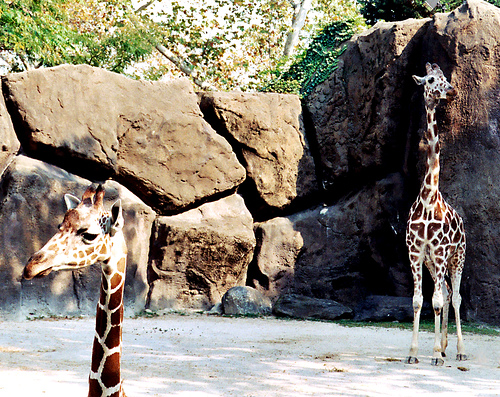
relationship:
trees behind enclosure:
[3, 0, 330, 75] [8, 8, 499, 382]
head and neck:
[23, 190, 126, 277] [87, 262, 127, 395]